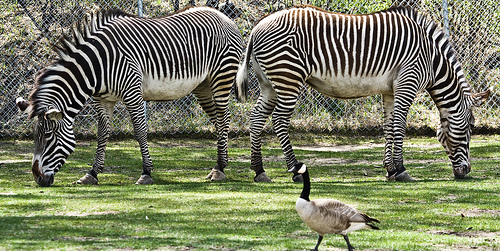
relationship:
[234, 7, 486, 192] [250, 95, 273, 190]
zebra has leg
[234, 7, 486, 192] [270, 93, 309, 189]
zebra has leg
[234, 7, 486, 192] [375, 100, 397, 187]
zebra has leg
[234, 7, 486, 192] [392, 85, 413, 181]
zebra has leg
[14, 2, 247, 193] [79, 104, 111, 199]
zebra has leg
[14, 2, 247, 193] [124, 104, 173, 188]
zebra has leg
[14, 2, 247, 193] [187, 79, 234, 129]
zebra has leg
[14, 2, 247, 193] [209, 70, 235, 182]
zebra has leg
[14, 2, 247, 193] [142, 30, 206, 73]
zebra has stripes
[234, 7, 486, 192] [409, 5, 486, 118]
zebra has mane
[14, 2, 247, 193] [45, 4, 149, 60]
zebra has mane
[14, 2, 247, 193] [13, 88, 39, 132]
zebra has ear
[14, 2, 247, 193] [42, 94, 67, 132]
zebra has ear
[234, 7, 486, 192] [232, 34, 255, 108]
zebra has tail